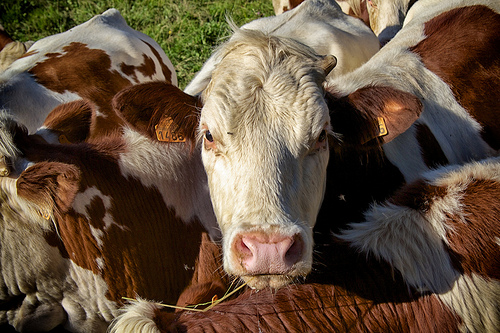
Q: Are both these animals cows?
A: Yes, all the animals are cows.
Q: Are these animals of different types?
A: No, all the animals are cows.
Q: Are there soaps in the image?
A: No, there are no soaps.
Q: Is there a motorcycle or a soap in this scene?
A: No, there are no soaps or motorcycles.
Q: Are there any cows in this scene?
A: Yes, there is a cow.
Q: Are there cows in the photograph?
A: Yes, there is a cow.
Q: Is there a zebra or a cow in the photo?
A: Yes, there is a cow.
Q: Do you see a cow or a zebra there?
A: Yes, there is a cow.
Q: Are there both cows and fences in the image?
A: No, there is a cow but no fences.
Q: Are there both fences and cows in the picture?
A: No, there is a cow but no fences.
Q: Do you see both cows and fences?
A: No, there is a cow but no fences.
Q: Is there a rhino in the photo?
A: No, there are no rhinos.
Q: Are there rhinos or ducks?
A: No, there are no rhinos or ducks.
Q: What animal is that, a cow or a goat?
A: That is a cow.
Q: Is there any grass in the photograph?
A: Yes, there is grass.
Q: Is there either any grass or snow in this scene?
A: Yes, there is grass.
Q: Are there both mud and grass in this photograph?
A: No, there is grass but no mud.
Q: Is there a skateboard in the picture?
A: No, there are no skateboards.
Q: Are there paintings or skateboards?
A: No, there are no skateboards or paintings.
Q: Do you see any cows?
A: Yes, there is a cow.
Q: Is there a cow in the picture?
A: Yes, there is a cow.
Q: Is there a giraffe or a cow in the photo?
A: Yes, there is a cow.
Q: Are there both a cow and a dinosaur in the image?
A: No, there is a cow but no dinosaurs.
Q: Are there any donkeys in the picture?
A: No, there are no donkeys.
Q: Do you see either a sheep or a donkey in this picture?
A: No, there are no donkeys or sheep.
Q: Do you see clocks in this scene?
A: No, there are no clocks.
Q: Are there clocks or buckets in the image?
A: No, there are no clocks or buckets.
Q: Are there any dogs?
A: No, there are no dogs.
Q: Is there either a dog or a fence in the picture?
A: No, there are no dogs or fences.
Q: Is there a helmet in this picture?
A: No, there are no helmets.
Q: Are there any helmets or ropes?
A: No, there are no helmets or ropes.